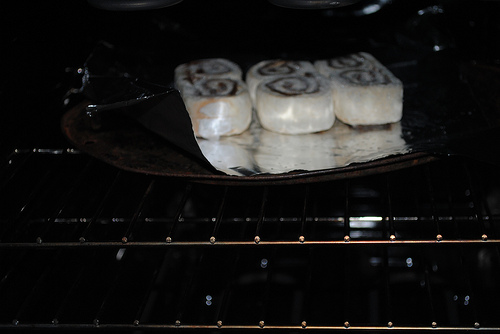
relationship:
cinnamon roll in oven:
[173, 57, 242, 79] [1, 1, 499, 332]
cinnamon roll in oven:
[176, 81, 252, 135] [1, 1, 499, 332]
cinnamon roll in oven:
[247, 59, 317, 77] [1, 1, 499, 332]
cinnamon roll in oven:
[251, 76, 335, 134] [1, 1, 499, 332]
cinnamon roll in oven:
[315, 53, 380, 66] [1, 1, 499, 332]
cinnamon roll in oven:
[328, 70, 402, 125] [1, 1, 499, 332]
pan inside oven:
[61, 51, 493, 185] [1, 1, 499, 332]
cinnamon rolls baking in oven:
[170, 52, 408, 141] [1, 1, 499, 332]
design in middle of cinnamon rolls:
[198, 62, 233, 77] [170, 52, 408, 141]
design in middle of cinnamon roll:
[198, 62, 233, 77] [173, 57, 242, 79]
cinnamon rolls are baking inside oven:
[170, 52, 408, 141] [1, 1, 499, 332]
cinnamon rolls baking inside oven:
[170, 52, 408, 141] [1, 1, 499, 332]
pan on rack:
[61, 51, 493, 185] [10, 148, 499, 287]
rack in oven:
[10, 148, 499, 287] [1, 1, 499, 332]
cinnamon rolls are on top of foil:
[170, 52, 408, 141] [70, 61, 493, 177]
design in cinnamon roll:
[198, 62, 233, 77] [173, 57, 242, 79]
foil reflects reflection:
[70, 61, 493, 177] [192, 133, 432, 179]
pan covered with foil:
[61, 51, 493, 185] [70, 61, 493, 177]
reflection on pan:
[192, 133, 432, 179] [61, 51, 493, 185]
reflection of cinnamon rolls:
[192, 133, 432, 179] [170, 52, 408, 141]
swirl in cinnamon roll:
[198, 62, 233, 77] [173, 57, 242, 79]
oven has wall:
[1, 1, 499, 332] [1, 1, 26, 332]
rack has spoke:
[10, 148, 499, 287] [2, 238, 17, 250]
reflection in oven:
[192, 133, 432, 179] [1, 1, 499, 332]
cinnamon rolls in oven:
[170, 52, 408, 141] [1, 1, 499, 332]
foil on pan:
[70, 61, 493, 177] [61, 51, 493, 185]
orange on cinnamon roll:
[195, 100, 238, 137] [176, 81, 252, 135]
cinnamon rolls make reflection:
[170, 52, 408, 141] [192, 133, 432, 179]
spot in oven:
[337, 199, 390, 235] [1, 1, 499, 332]